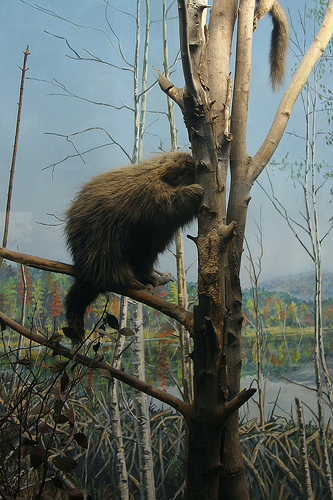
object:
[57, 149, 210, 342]
beaver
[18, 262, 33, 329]
tree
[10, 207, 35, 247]
clouds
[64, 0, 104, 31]
sky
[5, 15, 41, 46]
cloud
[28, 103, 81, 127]
cloud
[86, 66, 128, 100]
cloud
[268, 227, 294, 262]
cloud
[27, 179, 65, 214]
cloud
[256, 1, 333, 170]
branches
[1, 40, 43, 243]
branch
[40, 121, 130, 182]
branch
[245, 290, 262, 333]
tree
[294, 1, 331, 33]
sky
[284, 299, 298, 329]
tree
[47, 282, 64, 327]
tree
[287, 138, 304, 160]
sky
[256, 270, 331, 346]
mountain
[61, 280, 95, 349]
tail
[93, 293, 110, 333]
trees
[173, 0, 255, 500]
trunks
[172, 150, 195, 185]
face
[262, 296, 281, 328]
tree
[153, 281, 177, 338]
tree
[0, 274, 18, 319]
tree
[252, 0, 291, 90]
beaver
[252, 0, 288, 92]
animal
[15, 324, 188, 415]
branch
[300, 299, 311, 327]
tree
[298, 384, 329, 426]
lake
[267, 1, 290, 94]
tail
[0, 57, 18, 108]
clouds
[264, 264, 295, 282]
clouds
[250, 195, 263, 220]
clouds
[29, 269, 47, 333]
tree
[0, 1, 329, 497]
tree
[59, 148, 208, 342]
animal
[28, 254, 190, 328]
branch